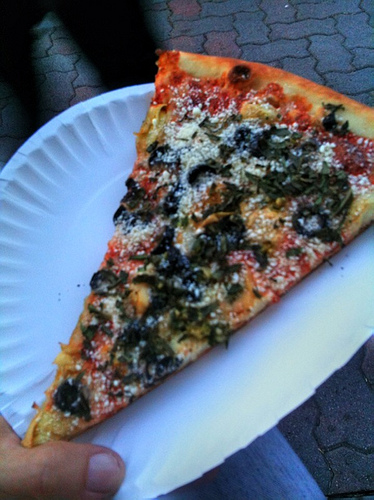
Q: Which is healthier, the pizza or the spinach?
A: The spinach is healthier than the pizza.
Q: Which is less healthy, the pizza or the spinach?
A: The pizza is less healthy than the spinach.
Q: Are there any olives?
A: Yes, there are olives.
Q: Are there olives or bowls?
A: Yes, there are olives.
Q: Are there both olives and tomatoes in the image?
A: No, there are olives but no tomatoes.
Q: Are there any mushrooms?
A: No, there are no mushrooms.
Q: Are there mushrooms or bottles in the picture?
A: No, there are no mushrooms or bottles.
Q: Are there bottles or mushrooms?
A: No, there are no mushrooms or bottles.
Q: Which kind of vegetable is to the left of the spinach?
A: The vegetables are olives.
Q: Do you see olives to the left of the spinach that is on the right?
A: Yes, there are olives to the left of the spinach.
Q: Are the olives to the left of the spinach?
A: Yes, the olives are to the left of the spinach.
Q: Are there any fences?
A: No, there are no fences.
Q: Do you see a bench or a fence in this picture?
A: No, there are no fences or benches.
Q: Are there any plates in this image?
A: Yes, there is a plate.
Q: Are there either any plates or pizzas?
A: Yes, there is a plate.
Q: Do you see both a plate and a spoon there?
A: No, there is a plate but no spoons.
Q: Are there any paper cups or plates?
A: Yes, there is a paper plate.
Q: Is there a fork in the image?
A: No, there are no forks.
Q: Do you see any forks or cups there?
A: No, there are no forks or cups.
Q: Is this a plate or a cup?
A: This is a plate.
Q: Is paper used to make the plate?
A: Yes, the plate is made of paper.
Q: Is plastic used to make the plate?
A: No, the plate is made of paper.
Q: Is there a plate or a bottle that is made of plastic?
A: No, there is a plate but it is made of paper.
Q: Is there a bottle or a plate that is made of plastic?
A: No, there is a plate but it is made of paper.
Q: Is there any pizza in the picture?
A: Yes, there is a pizza.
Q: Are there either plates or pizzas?
A: Yes, there is a pizza.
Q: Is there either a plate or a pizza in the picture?
A: Yes, there is a pizza.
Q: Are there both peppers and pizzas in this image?
A: No, there is a pizza but no peppers.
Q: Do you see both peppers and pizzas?
A: No, there is a pizza but no peppers.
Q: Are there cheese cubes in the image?
A: No, there are no cheese cubes.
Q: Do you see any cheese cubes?
A: No, there are no cheese cubes.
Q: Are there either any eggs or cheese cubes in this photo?
A: No, there are no cheese cubes or eggs.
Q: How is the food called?
A: The food is a pizza.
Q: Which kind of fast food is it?
A: The food is a pizza.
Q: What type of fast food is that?
A: This is a pizza.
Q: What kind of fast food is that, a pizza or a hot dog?
A: This is a pizza.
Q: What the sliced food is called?
A: The food is a pizza.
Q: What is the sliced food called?
A: The food is a pizza.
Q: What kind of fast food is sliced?
A: The fast food is a pizza.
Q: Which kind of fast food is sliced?
A: The fast food is a pizza.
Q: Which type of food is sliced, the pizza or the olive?
A: The pizza is sliced.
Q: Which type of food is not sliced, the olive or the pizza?
A: The olive is not sliced.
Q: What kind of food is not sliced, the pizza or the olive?
A: The olive is not sliced.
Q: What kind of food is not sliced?
A: The food is an olive.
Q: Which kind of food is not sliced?
A: The food is an olive.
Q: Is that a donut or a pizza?
A: That is a pizza.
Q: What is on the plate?
A: The pizza is on the plate.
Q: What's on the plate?
A: The pizza is on the plate.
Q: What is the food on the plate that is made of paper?
A: The food is a pizza.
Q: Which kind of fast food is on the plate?
A: The food is a pizza.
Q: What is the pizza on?
A: The pizza is on the plate.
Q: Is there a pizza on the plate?
A: Yes, there is a pizza on the plate.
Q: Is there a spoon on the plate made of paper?
A: No, there is a pizza on the plate.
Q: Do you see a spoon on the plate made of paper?
A: No, there is a pizza on the plate.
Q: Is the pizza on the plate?
A: Yes, the pizza is on the plate.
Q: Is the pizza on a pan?
A: No, the pizza is on the plate.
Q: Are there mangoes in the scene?
A: No, there are no mangoes.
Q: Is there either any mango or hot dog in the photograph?
A: No, there are no mangoes or hot dogs.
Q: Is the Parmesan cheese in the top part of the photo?
A: Yes, the Parmesan cheese is in the top of the image.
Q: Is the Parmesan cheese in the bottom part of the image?
A: No, the Parmesan cheese is in the top of the image.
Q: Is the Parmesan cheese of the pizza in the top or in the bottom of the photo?
A: The Parmesan cheese is in the top of the image.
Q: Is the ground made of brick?
A: Yes, the ground is made of brick.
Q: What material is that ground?
A: The ground is made of brick.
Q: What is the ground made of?
A: The ground is made of brick.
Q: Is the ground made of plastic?
A: No, the ground is made of brick.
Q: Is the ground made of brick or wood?
A: The ground is made of brick.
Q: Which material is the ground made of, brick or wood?
A: The ground is made of brick.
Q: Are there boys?
A: No, there are no boys.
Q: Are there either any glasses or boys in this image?
A: No, there are no boys or glasses.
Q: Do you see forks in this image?
A: No, there are no forks.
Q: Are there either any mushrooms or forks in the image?
A: No, there are no forks or mushrooms.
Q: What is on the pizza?
A: The tomato sauce is on the pizza.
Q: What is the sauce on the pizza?
A: The sauce is tomato sauce.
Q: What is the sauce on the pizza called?
A: The sauce is tomato sauce.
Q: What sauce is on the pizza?
A: The sauce is tomato sauce.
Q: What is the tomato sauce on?
A: The tomato sauce is on the pizza.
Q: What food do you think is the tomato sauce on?
A: The tomato sauce is on the pizza.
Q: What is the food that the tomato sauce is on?
A: The food is a pizza.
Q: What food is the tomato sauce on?
A: The tomato sauce is on the pizza.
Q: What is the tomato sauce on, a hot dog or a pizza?
A: The tomato sauce is on a pizza.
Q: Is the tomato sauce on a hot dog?
A: No, the tomato sauce is on the pizza.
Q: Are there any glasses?
A: No, there are no glasses.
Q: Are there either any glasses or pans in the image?
A: No, there are no glasses or pans.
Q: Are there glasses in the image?
A: No, there are no glasses.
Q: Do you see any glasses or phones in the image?
A: No, there are no glasses or phones.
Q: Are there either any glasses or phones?
A: No, there are no glasses or phones.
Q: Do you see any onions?
A: No, there are no onions.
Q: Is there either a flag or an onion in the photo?
A: No, there are no onions or flags.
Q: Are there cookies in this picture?
A: No, there are no cookies.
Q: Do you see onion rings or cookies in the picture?
A: No, there are no cookies or onion rings.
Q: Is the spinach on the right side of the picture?
A: Yes, the spinach is on the right of the image.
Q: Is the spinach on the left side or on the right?
A: The spinach is on the right of the image.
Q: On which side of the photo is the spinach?
A: The spinach is on the right of the image.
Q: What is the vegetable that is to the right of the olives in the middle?
A: The vegetable is spinach.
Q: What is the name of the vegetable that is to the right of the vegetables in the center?
A: The vegetable is spinach.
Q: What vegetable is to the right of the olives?
A: The vegetable is spinach.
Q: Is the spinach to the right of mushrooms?
A: No, the spinach is to the right of the olives.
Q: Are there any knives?
A: No, there are no knives.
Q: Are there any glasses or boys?
A: No, there are no glasses or boys.